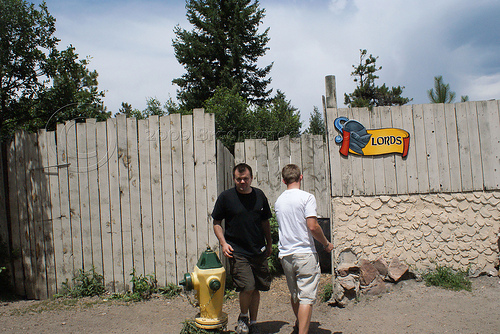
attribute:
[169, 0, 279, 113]
tree — tall, green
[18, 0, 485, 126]
cloud — white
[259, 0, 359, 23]
cloud — white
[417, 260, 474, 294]
grass — green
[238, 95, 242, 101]
leaf — green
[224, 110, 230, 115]
leaf — green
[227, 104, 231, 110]
leaf — green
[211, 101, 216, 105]
leaf — green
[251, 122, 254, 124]
leaf — green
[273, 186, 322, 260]
shirt — white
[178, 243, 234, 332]
fire hydrant — yellow, green, multi-colored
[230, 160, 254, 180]
hair — brown, dark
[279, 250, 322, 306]
shorts — khaki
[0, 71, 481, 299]
fence — wooden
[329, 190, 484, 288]
wall — low, stone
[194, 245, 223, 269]
top — green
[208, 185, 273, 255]
shirt — black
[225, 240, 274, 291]
shorts — brown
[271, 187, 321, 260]
t-shirt — white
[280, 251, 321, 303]
pants — tan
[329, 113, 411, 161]
sign — yellow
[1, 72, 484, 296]
gate — light tan, wooden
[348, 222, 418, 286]
rocks — pale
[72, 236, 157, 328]
bush — green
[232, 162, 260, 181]
hair — brown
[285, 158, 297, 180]
hair — blonde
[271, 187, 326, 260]
shirt — white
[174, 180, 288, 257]
shirt — black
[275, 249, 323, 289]
shorts — grey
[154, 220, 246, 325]
hydrant — yellow, green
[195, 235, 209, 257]
cap — green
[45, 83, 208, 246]
fence — grey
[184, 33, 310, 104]
pine — green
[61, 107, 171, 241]
fence — wooden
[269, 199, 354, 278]
shirt — white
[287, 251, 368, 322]
shorts — grey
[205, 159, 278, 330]
man — wearing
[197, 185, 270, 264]
shirt — black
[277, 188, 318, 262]
shirt — white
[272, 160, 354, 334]
man — wearing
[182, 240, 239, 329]
hydrant — YELLOW, green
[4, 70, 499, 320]
fence — brown, tall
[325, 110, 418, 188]
sign — yellow, blue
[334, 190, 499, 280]
wall — stone, tan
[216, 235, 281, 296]
shorts — brown 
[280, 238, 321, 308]
shorts — khaki 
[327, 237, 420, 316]
wall — broken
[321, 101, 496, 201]
wall — wooden 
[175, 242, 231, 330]
fire hydrant — yellow , green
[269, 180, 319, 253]
shirt — white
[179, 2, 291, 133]
leaves — green 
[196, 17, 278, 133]
leaves — green 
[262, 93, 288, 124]
leaves — green 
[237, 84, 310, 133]
leaves — green 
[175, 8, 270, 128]
leaves — green 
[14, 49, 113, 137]
leaves — green 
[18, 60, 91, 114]
leaves — green 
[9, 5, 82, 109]
leaves — green 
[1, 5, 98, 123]
leaves — green 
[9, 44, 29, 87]
leaves — green 